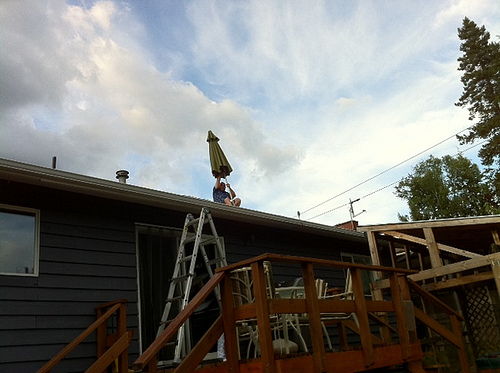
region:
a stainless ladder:
[163, 206, 230, 312]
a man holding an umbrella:
[192, 123, 252, 210]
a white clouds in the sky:
[167, 77, 273, 127]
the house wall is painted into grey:
[60, 238, 117, 294]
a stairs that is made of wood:
[373, 266, 449, 371]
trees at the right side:
[407, 70, 499, 223]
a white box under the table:
[266, 333, 300, 358]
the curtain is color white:
[147, 253, 166, 285]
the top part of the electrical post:
[341, 194, 373, 220]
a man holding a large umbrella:
[203, 129, 245, 211]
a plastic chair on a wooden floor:
[306, 264, 376, 351]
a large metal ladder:
[132, 207, 256, 366]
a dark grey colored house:
[2, 152, 468, 372]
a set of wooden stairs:
[3, 267, 238, 372]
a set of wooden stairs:
[330, 277, 478, 372]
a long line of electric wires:
[256, 92, 498, 237]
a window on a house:
[1, 205, 42, 279]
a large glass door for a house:
[129, 217, 242, 363]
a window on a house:
[336, 252, 386, 299]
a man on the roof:
[196, 130, 250, 209]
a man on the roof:
[185, 121, 265, 238]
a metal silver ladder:
[146, 204, 256, 354]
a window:
[3, 211, 33, 273]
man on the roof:
[208, 177, 240, 200]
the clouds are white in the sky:
[90, 59, 177, 133]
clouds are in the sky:
[236, 29, 347, 79]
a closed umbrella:
[201, 129, 237, 175]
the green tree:
[402, 170, 469, 211]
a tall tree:
[452, 16, 498, 113]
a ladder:
[177, 243, 202, 275]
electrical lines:
[363, 174, 378, 199]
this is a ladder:
[155, 199, 268, 366]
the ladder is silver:
[151, 195, 251, 371]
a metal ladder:
[159, 203, 259, 368]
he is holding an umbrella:
[188, 97, 269, 209]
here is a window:
[0, 194, 49, 328]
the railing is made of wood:
[66, 255, 231, 370]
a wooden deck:
[55, 241, 471, 370]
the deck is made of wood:
[52, 225, 484, 362]